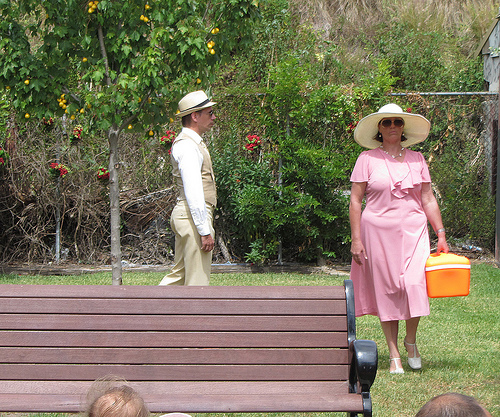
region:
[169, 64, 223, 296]
MAN WALKING IN PARK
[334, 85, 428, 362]
WOMAN WALKING IN PARK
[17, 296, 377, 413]
BROWN PARK BENCH IN PARK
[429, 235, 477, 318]
ORANGE LUNCHBOX IN HAND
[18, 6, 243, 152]
TREE GROWING BEHIND MAN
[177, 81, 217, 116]
WHITE HAT ON MAN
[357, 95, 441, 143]
WHITE HAT ON WOMAN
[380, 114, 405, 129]
SUNGLASSES ON WOMAN'S FACE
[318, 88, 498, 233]
CHAIN LINK FENCE BEHIND WOMAN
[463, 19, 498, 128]
SMALL SHED ON RIGHT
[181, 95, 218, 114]
hat on the head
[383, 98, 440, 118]
hat on the head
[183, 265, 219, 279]
the pants are tan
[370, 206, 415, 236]
the pink is dress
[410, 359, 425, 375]
the shoe is white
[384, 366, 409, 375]
the shoe is white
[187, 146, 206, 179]
the shirt is white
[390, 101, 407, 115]
the hat is tan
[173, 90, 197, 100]
the hat is tan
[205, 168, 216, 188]
the vest is tan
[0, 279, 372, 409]
A wood park bench.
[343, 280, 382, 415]
Black metal arm rest on bench.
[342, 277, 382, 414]
Black metal support on end of bench.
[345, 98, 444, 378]
Woman wearing a pink dress.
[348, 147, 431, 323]
A woman's pink dress.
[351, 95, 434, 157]
Woman wearing a wide brim hat.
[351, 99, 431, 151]
A wide brim hat.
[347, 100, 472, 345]
Woman carrying orange container.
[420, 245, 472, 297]
An orange container.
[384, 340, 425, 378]
Pair of white shoes.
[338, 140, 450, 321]
woman in pink dress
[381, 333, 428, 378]
tan strap sandal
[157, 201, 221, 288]
pair of tan pants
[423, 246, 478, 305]
white and orange plastic box with handle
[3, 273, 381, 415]
wooden bench with metal rails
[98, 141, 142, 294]
tree trunk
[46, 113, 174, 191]
red flowers in bushes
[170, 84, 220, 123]
tan fedora with black stripe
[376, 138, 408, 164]
white bead necklace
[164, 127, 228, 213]
tan vest on man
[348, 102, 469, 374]
the woman carrying a cooler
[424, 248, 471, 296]
the cooler in the woman's hand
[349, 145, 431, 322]
the pink dress on the woman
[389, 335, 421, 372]
the shoes on the woman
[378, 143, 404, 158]
the necklace on the woman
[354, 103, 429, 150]
the hat on the woman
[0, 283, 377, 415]
the empty bench on the grass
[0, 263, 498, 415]
the short green grass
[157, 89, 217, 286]
the man walking on the grass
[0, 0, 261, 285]
the tree near the man